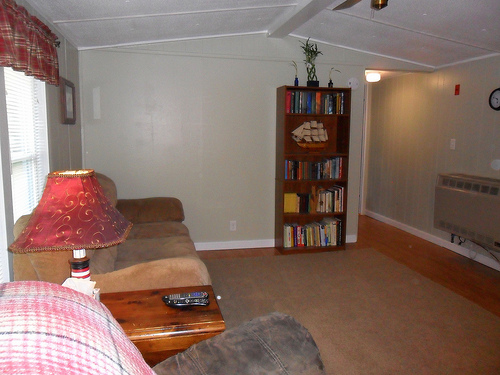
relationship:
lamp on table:
[7, 165, 133, 305] [95, 278, 224, 368]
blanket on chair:
[2, 278, 157, 374] [0, 275, 331, 374]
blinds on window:
[5, 66, 54, 220] [1, 3, 60, 260]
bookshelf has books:
[271, 82, 352, 255] [286, 86, 347, 116]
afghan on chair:
[2, 278, 157, 374] [0, 275, 331, 374]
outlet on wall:
[227, 219, 240, 234] [78, 34, 366, 251]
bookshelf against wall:
[271, 82, 352, 255] [78, 34, 366, 251]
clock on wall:
[488, 87, 499, 113] [364, 55, 499, 276]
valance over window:
[1, 1, 62, 85] [1, 3, 60, 260]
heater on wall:
[432, 167, 499, 259] [364, 55, 499, 276]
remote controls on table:
[162, 288, 212, 314] [95, 278, 224, 368]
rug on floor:
[204, 247, 500, 372] [196, 213, 500, 374]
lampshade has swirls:
[8, 165, 136, 256] [77, 205, 97, 225]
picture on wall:
[57, 73, 81, 126] [2, 1, 84, 289]